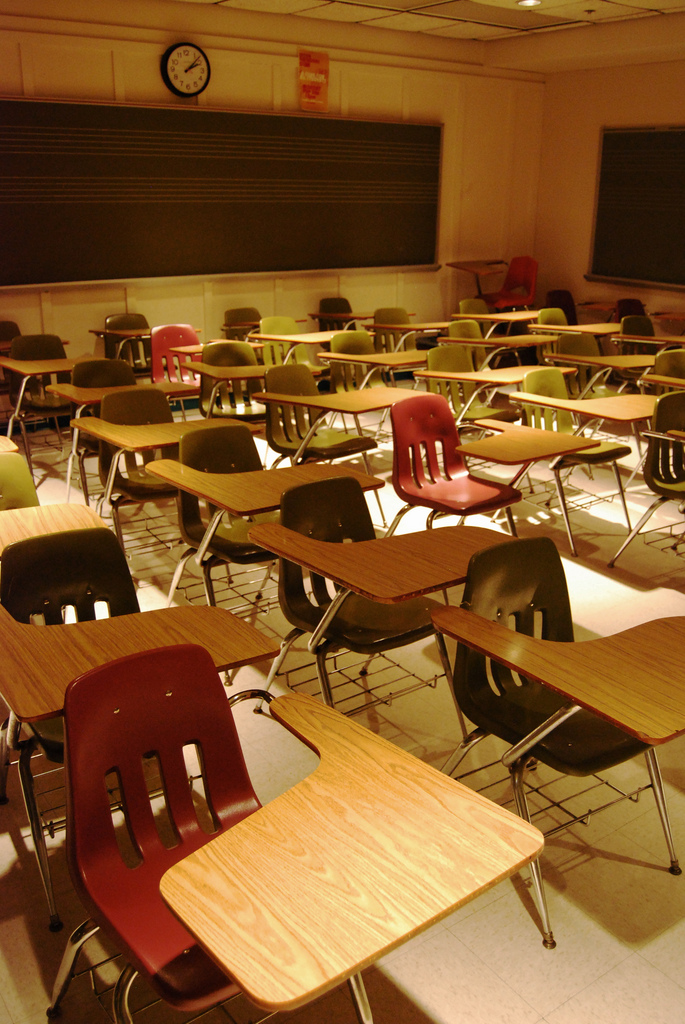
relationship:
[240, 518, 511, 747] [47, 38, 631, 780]
desk in classroom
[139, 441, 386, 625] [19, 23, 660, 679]
desk in classroom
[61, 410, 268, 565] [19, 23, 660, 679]
desk in classroom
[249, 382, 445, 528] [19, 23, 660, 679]
desk in classroom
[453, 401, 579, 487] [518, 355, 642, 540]
desk next to desk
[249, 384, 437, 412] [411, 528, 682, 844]
desk next to desk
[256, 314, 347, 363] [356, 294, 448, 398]
desk next to desk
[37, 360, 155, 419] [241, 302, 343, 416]
desk next to desk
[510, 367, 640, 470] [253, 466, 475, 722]
desk next to desk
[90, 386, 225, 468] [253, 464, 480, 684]
desk next to desk